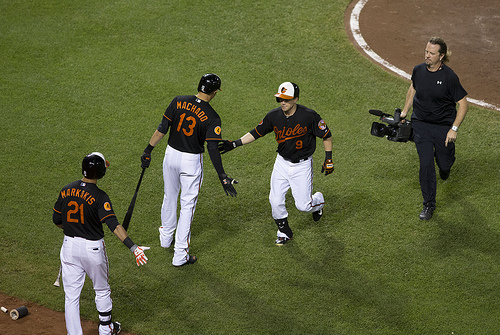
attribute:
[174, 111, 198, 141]
number — orange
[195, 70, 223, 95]
helmet — black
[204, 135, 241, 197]
gloves — black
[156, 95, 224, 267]
uniform — black, white, orange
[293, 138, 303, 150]
number — orange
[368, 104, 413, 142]
camera — black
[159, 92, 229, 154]
jersey — black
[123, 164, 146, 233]
baseball bat — black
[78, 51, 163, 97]
turf — green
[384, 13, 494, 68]
mound — dirt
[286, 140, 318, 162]
number — orange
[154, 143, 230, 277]
pants — white